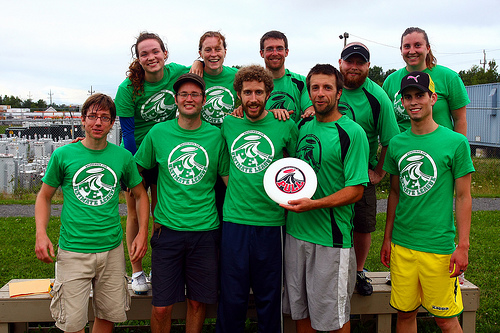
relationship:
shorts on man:
[382, 237, 471, 320] [29, 87, 151, 332]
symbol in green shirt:
[396, 151, 441, 196] [382, 124, 476, 254]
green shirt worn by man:
[382, 124, 476, 254] [381, 66, 462, 321]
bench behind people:
[0, 271, 480, 332] [28, 17, 478, 331]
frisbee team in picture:
[31, 22, 488, 331] [4, 5, 498, 323]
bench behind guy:
[0, 260, 483, 329] [380, 71, 476, 333]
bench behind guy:
[0, 260, 483, 329] [282, 63, 371, 332]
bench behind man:
[0, 260, 483, 329] [221, 64, 299, 333]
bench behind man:
[0, 260, 483, 329] [127, 73, 231, 333]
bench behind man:
[0, 260, 483, 329] [34, 92, 149, 332]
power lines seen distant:
[21, 72, 96, 105] [5, 80, 116, 110]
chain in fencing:
[1, 112, 123, 199] [6, 105, 76, 197]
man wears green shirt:
[29, 87, 151, 332] [40, 140, 143, 254]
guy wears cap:
[380, 71, 476, 333] [395, 72, 440, 94]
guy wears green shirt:
[380, 71, 476, 333] [381, 124, 475, 255]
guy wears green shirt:
[282, 63, 371, 332] [283, 114, 370, 250]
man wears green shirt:
[218, 66, 296, 331] [213, 110, 296, 228]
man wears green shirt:
[131, 72, 229, 329] [131, 114, 232, 231]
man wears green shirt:
[326, 40, 388, 292] [334, 73, 402, 152]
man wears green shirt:
[253, 29, 309, 121] [258, 67, 311, 116]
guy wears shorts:
[380, 71, 476, 333] [388, 237, 463, 318]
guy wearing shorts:
[380, 69, 474, 331] [388, 237, 463, 318]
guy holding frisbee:
[284, 63, 369, 331] [229, 135, 365, 217]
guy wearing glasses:
[380, 71, 476, 333] [370, 70, 456, 119]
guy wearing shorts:
[282, 63, 371, 332] [285, 235, 357, 327]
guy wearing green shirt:
[380, 71, 476, 333] [382, 124, 476, 254]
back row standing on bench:
[103, 24, 460, 112] [122, 283, 429, 328]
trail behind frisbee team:
[0, 197, 500, 221] [34, 27, 476, 333]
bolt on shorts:
[452, 273, 462, 304] [388, 237, 463, 318]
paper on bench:
[8, 279, 51, 296] [1, 271, 478, 331]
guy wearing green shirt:
[282, 63, 371, 332] [285, 115, 369, 249]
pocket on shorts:
[44, 270, 83, 332] [44, 236, 137, 331]